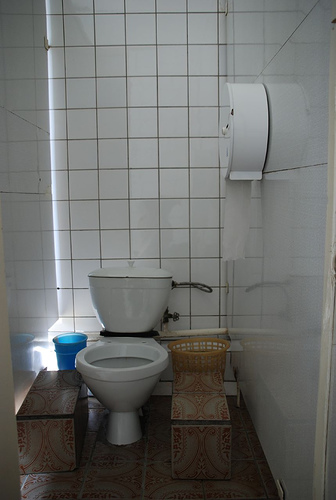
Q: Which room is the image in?
A: It is at the bathroom.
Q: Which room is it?
A: It is a bathroom.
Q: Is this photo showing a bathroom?
A: Yes, it is showing a bathroom.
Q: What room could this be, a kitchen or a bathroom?
A: It is a bathroom.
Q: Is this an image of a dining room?
A: No, the picture is showing a bathroom.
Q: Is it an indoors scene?
A: Yes, it is indoors.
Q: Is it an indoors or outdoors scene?
A: It is indoors.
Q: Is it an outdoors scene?
A: No, it is indoors.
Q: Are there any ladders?
A: No, there are no ladders.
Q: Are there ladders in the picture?
A: No, there are no ladders.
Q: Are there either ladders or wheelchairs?
A: No, there are no ladders or wheelchairs.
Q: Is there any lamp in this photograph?
A: No, there are no lamps.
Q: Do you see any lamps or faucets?
A: No, there are no lamps or faucets.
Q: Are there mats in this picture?
A: No, there are no mats.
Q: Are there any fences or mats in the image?
A: No, there are no mats or fences.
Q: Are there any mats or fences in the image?
A: No, there are no mats or fences.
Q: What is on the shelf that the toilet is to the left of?
A: The basket is on the shelf.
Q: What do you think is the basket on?
A: The basket is on the shelf.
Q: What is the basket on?
A: The basket is on the shelf.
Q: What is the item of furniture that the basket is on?
A: The piece of furniture is a shelf.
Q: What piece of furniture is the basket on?
A: The basket is on the shelf.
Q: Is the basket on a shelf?
A: Yes, the basket is on a shelf.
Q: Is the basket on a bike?
A: No, the basket is on a shelf.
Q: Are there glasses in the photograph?
A: No, there are no glasses.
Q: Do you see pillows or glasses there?
A: No, there are no glasses or pillows.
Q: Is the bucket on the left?
A: Yes, the bucket is on the left of the image.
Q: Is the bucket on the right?
A: No, the bucket is on the left of the image.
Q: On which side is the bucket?
A: The bucket is on the left of the image.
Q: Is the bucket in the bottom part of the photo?
A: Yes, the bucket is in the bottom of the image.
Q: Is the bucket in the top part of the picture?
A: No, the bucket is in the bottom of the image.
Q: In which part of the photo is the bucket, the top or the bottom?
A: The bucket is in the bottom of the image.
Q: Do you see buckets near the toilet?
A: Yes, there is a bucket near the toilet.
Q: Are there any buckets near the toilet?
A: Yes, there is a bucket near the toilet.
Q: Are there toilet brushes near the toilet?
A: No, there is a bucket near the toilet.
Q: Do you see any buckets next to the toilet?
A: Yes, there is a bucket next to the toilet.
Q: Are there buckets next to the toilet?
A: Yes, there is a bucket next to the toilet.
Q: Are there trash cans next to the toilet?
A: No, there is a bucket next to the toilet.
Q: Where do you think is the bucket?
A: The bucket is on the floor.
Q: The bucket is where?
A: The bucket is on the floor.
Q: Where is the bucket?
A: The bucket is on the floor.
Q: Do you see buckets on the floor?
A: Yes, there is a bucket on the floor.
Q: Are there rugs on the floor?
A: No, there is a bucket on the floor.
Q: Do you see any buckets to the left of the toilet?
A: Yes, there is a bucket to the left of the toilet.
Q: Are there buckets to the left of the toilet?
A: Yes, there is a bucket to the left of the toilet.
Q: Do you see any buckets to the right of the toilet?
A: No, the bucket is to the left of the toilet.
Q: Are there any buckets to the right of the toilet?
A: No, the bucket is to the left of the toilet.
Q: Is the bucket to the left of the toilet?
A: Yes, the bucket is to the left of the toilet.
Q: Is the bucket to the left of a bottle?
A: No, the bucket is to the left of the toilet.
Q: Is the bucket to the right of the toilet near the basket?
A: No, the bucket is to the left of the toilet.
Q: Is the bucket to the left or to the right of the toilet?
A: The bucket is to the left of the toilet.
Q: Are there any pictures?
A: No, there are no pictures.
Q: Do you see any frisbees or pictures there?
A: No, there are no pictures or frisbees.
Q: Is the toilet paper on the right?
A: Yes, the toilet paper is on the right of the image.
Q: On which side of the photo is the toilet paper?
A: The toilet paper is on the right of the image.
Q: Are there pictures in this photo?
A: No, there are no pictures.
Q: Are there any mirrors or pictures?
A: No, there are no pictures or mirrors.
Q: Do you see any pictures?
A: No, there are no pictures.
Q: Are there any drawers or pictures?
A: No, there are no pictures or drawers.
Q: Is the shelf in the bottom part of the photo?
A: Yes, the shelf is in the bottom of the image.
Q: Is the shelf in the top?
A: No, the shelf is in the bottom of the image.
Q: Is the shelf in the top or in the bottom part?
A: The shelf is in the bottom of the image.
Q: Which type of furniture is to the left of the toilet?
A: The piece of furniture is a shelf.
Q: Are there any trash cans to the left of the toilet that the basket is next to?
A: No, there is a shelf to the left of the toilet.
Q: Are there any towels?
A: No, there are no towels.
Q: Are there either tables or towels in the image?
A: No, there are no towels or tables.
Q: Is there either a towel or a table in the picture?
A: No, there are no towels or tables.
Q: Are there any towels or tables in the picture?
A: No, there are no towels or tables.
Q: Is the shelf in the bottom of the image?
A: Yes, the shelf is in the bottom of the image.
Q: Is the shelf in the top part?
A: No, the shelf is in the bottom of the image.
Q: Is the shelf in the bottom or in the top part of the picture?
A: The shelf is in the bottom of the image.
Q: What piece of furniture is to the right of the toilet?
A: The piece of furniture is a shelf.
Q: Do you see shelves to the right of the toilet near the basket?
A: Yes, there is a shelf to the right of the toilet.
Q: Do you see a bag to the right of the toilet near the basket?
A: No, there is a shelf to the right of the toilet.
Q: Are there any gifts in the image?
A: No, there are no gifts.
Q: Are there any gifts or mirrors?
A: No, there are no gifts or mirrors.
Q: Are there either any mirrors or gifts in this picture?
A: No, there are no gifts or mirrors.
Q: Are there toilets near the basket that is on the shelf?
A: Yes, there is a toilet near the basket.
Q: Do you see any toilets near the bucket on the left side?
A: Yes, there is a toilet near the bucket.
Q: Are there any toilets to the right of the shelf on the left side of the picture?
A: Yes, there is a toilet to the right of the shelf.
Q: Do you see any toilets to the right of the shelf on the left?
A: Yes, there is a toilet to the right of the shelf.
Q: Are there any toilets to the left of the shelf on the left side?
A: No, the toilet is to the right of the shelf.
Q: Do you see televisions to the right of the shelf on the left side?
A: No, there is a toilet to the right of the shelf.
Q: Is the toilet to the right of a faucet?
A: No, the toilet is to the right of the shelf.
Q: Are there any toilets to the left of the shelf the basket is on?
A: Yes, there is a toilet to the left of the shelf.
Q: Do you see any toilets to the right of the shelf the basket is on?
A: No, the toilet is to the left of the shelf.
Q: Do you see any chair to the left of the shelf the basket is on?
A: No, there is a toilet to the left of the shelf.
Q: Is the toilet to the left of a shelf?
A: Yes, the toilet is to the left of a shelf.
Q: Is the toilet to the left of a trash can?
A: No, the toilet is to the left of a shelf.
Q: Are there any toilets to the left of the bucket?
A: No, the toilet is to the right of the bucket.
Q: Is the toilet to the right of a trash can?
A: No, the toilet is to the right of the bucket.